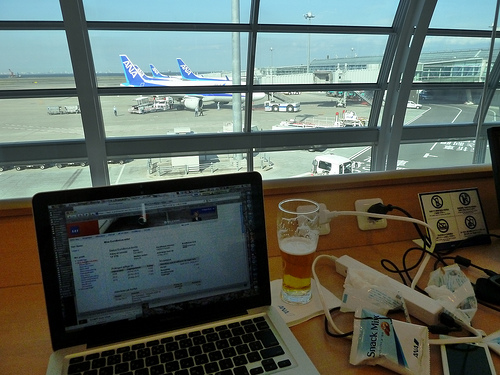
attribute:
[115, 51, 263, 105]
plane — blue, white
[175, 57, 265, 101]
plane — blue, white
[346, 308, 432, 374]
snack pack — blue, white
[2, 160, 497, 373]
desk — brown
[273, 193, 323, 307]
glass — half full, clear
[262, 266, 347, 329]
notepad — white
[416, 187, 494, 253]
sign — small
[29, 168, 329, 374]
laptop — black, open, grey, on, white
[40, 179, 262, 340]
screen — on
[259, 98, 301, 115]
loading vehicle — small, white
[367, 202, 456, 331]
electrical cord — black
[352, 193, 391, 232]
outlet — white, here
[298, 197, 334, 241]
outlet — white, here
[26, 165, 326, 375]
computer — laptop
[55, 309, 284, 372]
keyboard — black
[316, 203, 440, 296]
electrical cord — white, plugged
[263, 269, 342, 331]
napkin — white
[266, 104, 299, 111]
stripe — blue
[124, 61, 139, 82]
logo — blue, white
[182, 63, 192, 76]
logo — blue, white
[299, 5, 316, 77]
light — tall, white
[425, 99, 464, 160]
line — white